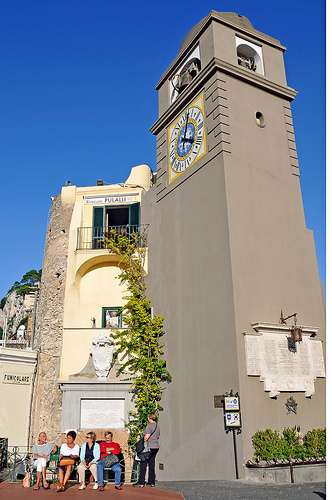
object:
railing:
[76, 225, 146, 248]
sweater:
[80, 441, 101, 463]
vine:
[97, 223, 171, 463]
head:
[104, 431, 113, 443]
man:
[96, 430, 123, 492]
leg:
[113, 463, 123, 491]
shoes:
[98, 485, 104, 492]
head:
[85, 432, 96, 443]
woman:
[77, 431, 100, 490]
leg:
[78, 463, 87, 491]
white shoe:
[92, 481, 99, 491]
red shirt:
[100, 441, 120, 459]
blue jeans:
[97, 458, 123, 486]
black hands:
[183, 113, 190, 148]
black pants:
[137, 448, 158, 486]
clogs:
[132, 479, 146, 487]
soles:
[133, 484, 144, 487]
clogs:
[145, 480, 155, 487]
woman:
[132, 409, 161, 487]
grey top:
[144, 421, 159, 451]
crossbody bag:
[135, 440, 150, 463]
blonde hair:
[149, 412, 158, 420]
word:
[86, 200, 89, 204]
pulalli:
[104, 196, 126, 203]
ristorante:
[85, 195, 104, 206]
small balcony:
[75, 221, 150, 252]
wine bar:
[90, 201, 140, 245]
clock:
[167, 93, 206, 183]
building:
[142, 9, 324, 483]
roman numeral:
[196, 121, 205, 131]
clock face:
[168, 107, 205, 173]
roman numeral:
[195, 135, 203, 147]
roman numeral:
[195, 110, 201, 121]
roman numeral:
[184, 159, 189, 168]